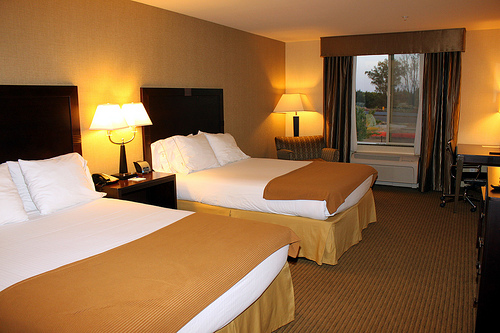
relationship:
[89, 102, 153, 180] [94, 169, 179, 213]
double lamp on nightstand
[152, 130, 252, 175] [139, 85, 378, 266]
pillows on bed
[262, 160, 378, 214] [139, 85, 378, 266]
blanket on bed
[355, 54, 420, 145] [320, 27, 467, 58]
window under valance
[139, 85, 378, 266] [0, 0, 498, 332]
bed in room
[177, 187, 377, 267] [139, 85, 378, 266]
dust ruffle for bed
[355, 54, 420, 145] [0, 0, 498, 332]
window in room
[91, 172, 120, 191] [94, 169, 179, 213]
phone on nightstand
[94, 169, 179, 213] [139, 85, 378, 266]
nightstand next to bed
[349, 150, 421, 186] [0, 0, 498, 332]
heat and ac unit in room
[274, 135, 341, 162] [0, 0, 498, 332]
chair in room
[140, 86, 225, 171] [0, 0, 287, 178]
headboard on wall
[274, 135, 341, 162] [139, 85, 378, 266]
chair next to bed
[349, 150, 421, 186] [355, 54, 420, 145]
heat and ac unit under window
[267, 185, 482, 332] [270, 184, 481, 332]
carpet has lines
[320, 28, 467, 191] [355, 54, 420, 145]
curtains on window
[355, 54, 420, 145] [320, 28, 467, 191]
window near curtains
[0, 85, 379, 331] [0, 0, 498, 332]
beds in room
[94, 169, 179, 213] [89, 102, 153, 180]
nightstand under double lamp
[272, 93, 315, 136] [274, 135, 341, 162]
lamp behind chair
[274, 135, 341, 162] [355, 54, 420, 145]
chair by window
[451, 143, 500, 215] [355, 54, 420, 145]
desk by window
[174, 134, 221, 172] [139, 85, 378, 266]
pillow on bed